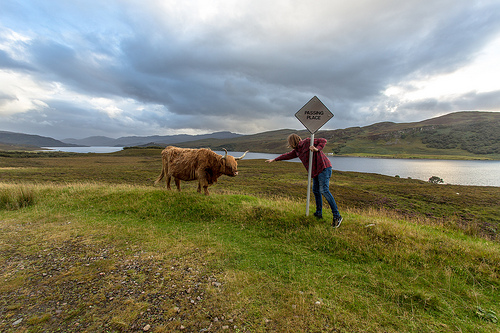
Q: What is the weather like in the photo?
A: It is cloudy.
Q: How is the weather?
A: It is cloudy.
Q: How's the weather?
A: It is cloudy.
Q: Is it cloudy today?
A: Yes, it is cloudy.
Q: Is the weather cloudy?
A: Yes, it is cloudy.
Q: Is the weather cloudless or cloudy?
A: It is cloudy.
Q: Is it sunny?
A: No, it is cloudy.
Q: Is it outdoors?
A: Yes, it is outdoors.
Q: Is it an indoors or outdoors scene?
A: It is outdoors.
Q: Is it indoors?
A: No, it is outdoors.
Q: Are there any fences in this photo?
A: No, there are no fences.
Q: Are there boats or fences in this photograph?
A: No, there are no fences or boats.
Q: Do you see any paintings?
A: No, there are no paintings.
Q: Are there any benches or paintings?
A: No, there are no paintings or benches.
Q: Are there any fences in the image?
A: No, there are no fences.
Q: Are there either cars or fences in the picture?
A: No, there are no fences or cars.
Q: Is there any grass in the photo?
A: Yes, there is grass.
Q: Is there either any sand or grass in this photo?
A: Yes, there is grass.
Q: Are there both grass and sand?
A: No, there is grass but no sand.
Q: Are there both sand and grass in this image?
A: No, there is grass but no sand.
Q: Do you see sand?
A: No, there is no sand.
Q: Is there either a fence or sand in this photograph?
A: No, there are no sand or fences.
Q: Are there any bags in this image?
A: No, there are no bags.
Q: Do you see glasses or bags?
A: No, there are no bags or glasses.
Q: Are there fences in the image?
A: No, there are no fences.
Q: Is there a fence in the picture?
A: No, there are no fences.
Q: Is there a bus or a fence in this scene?
A: No, there are no fences or buses.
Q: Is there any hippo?
A: No, there are no hippos.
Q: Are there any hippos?
A: No, there are no hippos.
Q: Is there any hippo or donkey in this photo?
A: No, there are no hippos or donkeys.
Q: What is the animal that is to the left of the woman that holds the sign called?
A: The animal is a bull.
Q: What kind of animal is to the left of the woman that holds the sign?
A: The animal is a bull.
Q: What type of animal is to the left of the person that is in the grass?
A: The animal is a bull.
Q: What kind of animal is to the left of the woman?
A: The animal is a bull.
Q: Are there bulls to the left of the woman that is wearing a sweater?
A: Yes, there is a bull to the left of the woman.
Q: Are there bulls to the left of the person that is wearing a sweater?
A: Yes, there is a bull to the left of the woman.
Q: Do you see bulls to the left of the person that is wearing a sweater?
A: Yes, there is a bull to the left of the woman.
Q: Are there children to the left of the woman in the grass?
A: No, there is a bull to the left of the woman.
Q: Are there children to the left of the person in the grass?
A: No, there is a bull to the left of the woman.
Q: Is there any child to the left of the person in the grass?
A: No, there is a bull to the left of the woman.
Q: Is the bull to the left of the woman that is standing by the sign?
A: Yes, the bull is to the left of the woman.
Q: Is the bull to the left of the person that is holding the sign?
A: Yes, the bull is to the left of the woman.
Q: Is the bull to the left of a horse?
A: No, the bull is to the left of the woman.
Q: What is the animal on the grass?
A: The animal is a bull.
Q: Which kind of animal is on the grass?
A: The animal is a bull.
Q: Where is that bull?
A: The bull is on the grass.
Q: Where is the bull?
A: The bull is on the grass.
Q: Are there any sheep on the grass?
A: No, there is a bull on the grass.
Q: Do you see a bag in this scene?
A: No, there are no bags.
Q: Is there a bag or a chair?
A: No, there are no bags or chairs.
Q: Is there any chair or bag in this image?
A: No, there are no bags or chairs.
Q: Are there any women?
A: Yes, there is a woman.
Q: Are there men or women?
A: Yes, there is a woman.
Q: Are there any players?
A: No, there are no players.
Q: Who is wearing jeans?
A: The woman is wearing jeans.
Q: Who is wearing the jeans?
A: The woman is wearing jeans.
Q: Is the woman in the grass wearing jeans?
A: Yes, the woman is wearing jeans.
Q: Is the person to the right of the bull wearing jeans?
A: Yes, the woman is wearing jeans.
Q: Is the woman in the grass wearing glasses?
A: No, the woman is wearing jeans.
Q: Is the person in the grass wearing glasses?
A: No, the woman is wearing jeans.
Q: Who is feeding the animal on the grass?
A: The woman is feeding the bull.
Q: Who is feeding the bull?
A: The woman is feeding the bull.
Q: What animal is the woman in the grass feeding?
A: The woman is feeding the bull.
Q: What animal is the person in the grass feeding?
A: The woman is feeding the bull.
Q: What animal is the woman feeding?
A: The woman is feeding the bull.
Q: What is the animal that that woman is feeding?
A: The animal is a bull.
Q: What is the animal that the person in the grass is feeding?
A: The animal is a bull.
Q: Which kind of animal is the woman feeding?
A: The woman is feeding the bull.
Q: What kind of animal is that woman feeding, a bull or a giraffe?
A: The woman is feeding a bull.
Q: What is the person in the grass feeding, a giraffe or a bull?
A: The woman is feeding a bull.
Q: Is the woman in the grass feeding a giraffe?
A: No, the woman is feeding the bull.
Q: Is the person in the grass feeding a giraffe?
A: No, the woman is feeding the bull.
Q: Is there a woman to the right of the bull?
A: Yes, there is a woman to the right of the bull.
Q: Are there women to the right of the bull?
A: Yes, there is a woman to the right of the bull.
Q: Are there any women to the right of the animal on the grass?
A: Yes, there is a woman to the right of the bull.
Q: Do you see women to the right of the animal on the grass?
A: Yes, there is a woman to the right of the bull.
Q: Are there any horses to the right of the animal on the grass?
A: No, there is a woman to the right of the bull.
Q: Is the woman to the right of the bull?
A: Yes, the woman is to the right of the bull.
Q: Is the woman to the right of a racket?
A: No, the woman is to the right of the bull.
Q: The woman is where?
A: The woman is in the grass.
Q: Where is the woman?
A: The woman is in the grass.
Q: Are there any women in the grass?
A: Yes, there is a woman in the grass.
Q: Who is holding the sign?
A: The woman is holding the sign.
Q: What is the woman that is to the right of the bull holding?
A: The woman is holding the sign.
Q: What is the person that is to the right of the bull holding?
A: The woman is holding the sign.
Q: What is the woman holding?
A: The woman is holding the sign.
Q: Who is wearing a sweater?
A: The woman is wearing a sweater.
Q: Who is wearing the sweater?
A: The woman is wearing a sweater.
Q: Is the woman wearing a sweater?
A: Yes, the woman is wearing a sweater.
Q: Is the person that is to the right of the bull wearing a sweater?
A: Yes, the woman is wearing a sweater.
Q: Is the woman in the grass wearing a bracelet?
A: No, the woman is wearing a sweater.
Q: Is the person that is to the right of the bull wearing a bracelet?
A: No, the woman is wearing a sweater.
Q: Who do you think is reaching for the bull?
A: The woman is reaching for the bull.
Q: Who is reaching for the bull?
A: The woman is reaching for the bull.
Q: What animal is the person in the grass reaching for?
A: The woman is reaching for the bull.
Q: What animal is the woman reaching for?
A: The woman is reaching for the bull.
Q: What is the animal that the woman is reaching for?
A: The animal is a bull.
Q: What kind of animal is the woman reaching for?
A: The woman is reaching for the bull.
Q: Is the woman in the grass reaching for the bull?
A: Yes, the woman is reaching for the bull.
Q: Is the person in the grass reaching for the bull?
A: Yes, the woman is reaching for the bull.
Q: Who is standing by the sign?
A: The woman is standing by the sign.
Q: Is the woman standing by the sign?
A: Yes, the woman is standing by the sign.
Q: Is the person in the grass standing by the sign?
A: Yes, the woman is standing by the sign.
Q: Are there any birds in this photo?
A: No, there are no birds.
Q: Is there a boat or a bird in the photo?
A: No, there are no birds or boats.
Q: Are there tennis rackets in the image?
A: No, there are no tennis rackets.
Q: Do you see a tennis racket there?
A: No, there are no rackets.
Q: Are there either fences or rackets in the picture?
A: No, there are no rackets or fences.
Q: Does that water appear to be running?
A: Yes, the water is running.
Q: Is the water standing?
A: No, the water is running.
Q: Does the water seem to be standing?
A: No, the water is running.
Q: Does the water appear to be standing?
A: No, the water is running.